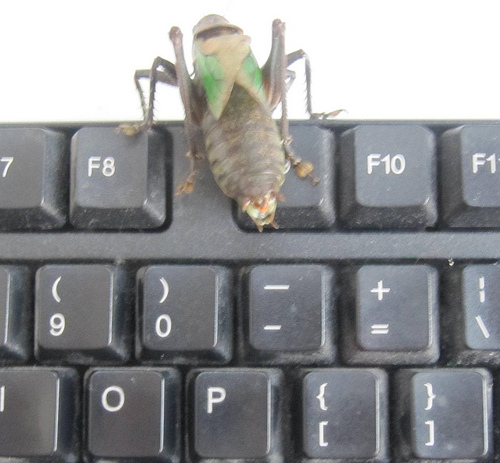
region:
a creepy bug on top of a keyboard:
[118, 3, 356, 235]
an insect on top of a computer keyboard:
[113, 0, 350, 241]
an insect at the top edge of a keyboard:
[119, 14, 344, 242]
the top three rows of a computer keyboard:
[2, 118, 499, 455]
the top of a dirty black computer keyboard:
[1, 121, 499, 461]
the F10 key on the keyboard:
[339, 123, 441, 227]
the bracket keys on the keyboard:
[300, 366, 499, 457]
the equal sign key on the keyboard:
[341, 260, 449, 365]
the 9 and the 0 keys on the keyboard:
[33, 260, 237, 362]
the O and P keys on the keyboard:
[81, 362, 293, 461]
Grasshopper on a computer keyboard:
[119, 3, 338, 219]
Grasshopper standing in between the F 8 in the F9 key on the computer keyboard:
[88, 20, 333, 232]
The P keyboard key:
[184, 356, 295, 461]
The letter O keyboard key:
[84, 366, 165, 459]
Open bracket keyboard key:
[307, 372, 387, 455]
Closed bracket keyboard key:
[396, 367, 493, 460]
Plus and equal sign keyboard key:
[344, 258, 438, 360]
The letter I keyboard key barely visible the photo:
[1, 367, 75, 459]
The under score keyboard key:
[252, 267, 325, 359]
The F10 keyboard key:
[346, 118, 436, 222]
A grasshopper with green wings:
[120, 5, 345, 250]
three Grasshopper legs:
[116, 20, 201, 210]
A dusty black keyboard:
[0, 121, 495, 457]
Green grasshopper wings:
[190, 25, 270, 120]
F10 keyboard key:
[332, 115, 442, 230]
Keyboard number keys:
[27, 260, 228, 357]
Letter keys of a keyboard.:
[0, 362, 287, 457]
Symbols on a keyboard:
[252, 265, 487, 460]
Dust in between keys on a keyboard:
[0, 345, 495, 371]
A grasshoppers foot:
[281, 135, 327, 195]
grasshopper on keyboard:
[113, 15, 325, 293]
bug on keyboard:
[94, 94, 316, 279]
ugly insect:
[96, 70, 368, 215]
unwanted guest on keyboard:
[22, 27, 357, 235]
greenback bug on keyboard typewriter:
[20, 10, 405, 221]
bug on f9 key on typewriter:
[78, 106, 324, 261]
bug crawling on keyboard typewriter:
[157, 155, 322, 265]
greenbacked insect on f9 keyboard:
[190, 27, 397, 247]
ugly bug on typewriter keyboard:
[225, 0, 268, 268]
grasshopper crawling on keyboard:
[171, 2, 336, 254]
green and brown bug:
[130, 9, 338, 227]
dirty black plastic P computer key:
[187, 366, 282, 460]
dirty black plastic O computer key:
[84, 364, 185, 458]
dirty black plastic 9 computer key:
[35, 264, 125, 359]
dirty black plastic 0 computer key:
[141, 264, 231, 355]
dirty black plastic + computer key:
[351, 261, 436, 363]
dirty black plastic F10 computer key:
[340, 122, 436, 227]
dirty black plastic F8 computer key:
[71, 122, 168, 223]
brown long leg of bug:
[167, 22, 207, 199]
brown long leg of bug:
[263, 16, 302, 181]